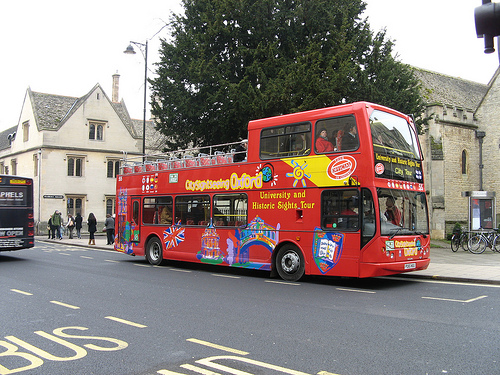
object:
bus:
[114, 101, 433, 284]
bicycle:
[469, 231, 499, 252]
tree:
[151, 4, 433, 113]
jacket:
[317, 137, 333, 151]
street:
[2, 283, 500, 374]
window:
[67, 156, 83, 175]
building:
[10, 69, 137, 236]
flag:
[155, 229, 189, 247]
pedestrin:
[85, 214, 96, 245]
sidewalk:
[71, 237, 111, 248]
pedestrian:
[105, 215, 114, 243]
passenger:
[231, 136, 247, 161]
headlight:
[395, 249, 405, 259]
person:
[49, 211, 65, 239]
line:
[47, 299, 81, 311]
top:
[117, 130, 247, 172]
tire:
[146, 234, 163, 265]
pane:
[315, 115, 357, 153]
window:
[325, 191, 358, 229]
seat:
[195, 151, 213, 169]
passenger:
[315, 131, 335, 156]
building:
[432, 64, 500, 237]